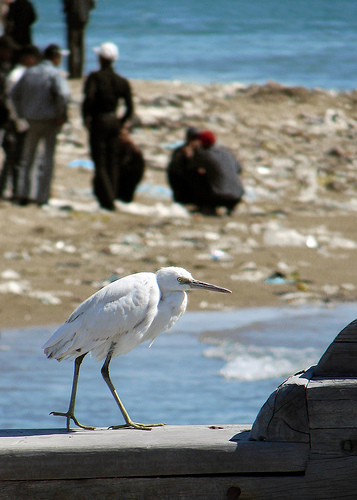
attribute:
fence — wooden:
[2, 322, 356, 496]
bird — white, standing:
[44, 266, 232, 436]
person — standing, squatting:
[190, 132, 244, 213]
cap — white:
[92, 45, 117, 59]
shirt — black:
[81, 68, 133, 127]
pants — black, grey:
[88, 115, 121, 209]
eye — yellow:
[180, 278, 188, 286]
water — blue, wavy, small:
[27, 2, 354, 95]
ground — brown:
[1, 76, 350, 332]